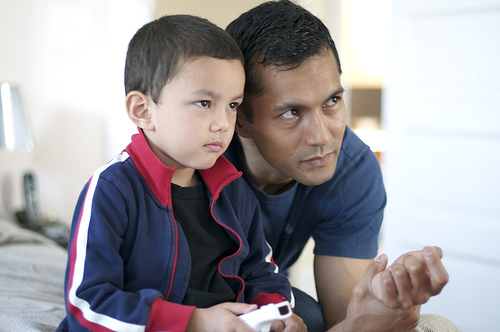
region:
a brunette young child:
[63, 14, 295, 325]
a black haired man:
[225, 6, 452, 325]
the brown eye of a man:
[279, 107, 294, 119]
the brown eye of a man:
[324, 93, 340, 106]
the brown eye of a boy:
[193, 97, 207, 109]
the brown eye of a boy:
[229, 100, 241, 110]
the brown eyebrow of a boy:
[194, 84, 217, 100]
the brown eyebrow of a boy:
[230, 93, 243, 103]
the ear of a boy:
[127, 90, 159, 127]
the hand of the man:
[347, 247, 420, 329]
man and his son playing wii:
[112, 7, 387, 252]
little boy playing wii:
[116, 7, 286, 329]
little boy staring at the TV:
[112, 12, 242, 182]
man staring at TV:
[235, 12, 454, 291]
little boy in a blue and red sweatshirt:
[83, 12, 248, 312]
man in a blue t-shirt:
[238, 4, 408, 285]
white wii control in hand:
[227, 295, 300, 327]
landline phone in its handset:
[16, 163, 55, 226]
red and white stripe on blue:
[66, 178, 102, 319]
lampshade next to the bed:
[5, 78, 38, 154]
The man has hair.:
[225, 0, 355, 197]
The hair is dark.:
[215, 2, 361, 194]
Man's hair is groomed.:
[217, 2, 347, 171]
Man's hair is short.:
[216, 0, 366, 190]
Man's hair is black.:
[221, 0, 356, 189]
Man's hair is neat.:
[215, 1, 354, 197]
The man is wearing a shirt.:
[213, 0, 393, 298]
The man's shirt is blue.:
[214, 0, 392, 300]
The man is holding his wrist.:
[223, 0, 459, 330]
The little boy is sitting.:
[27, 9, 313, 329]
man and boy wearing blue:
[89, 18, 442, 312]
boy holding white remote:
[105, 41, 331, 328]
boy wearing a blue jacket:
[96, 32, 318, 322]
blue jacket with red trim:
[65, 142, 325, 328]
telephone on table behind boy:
[19, 163, 81, 264]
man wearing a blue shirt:
[236, 114, 425, 288]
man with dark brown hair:
[218, 6, 385, 203]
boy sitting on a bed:
[11, 17, 263, 329]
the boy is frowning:
[108, 18, 260, 175]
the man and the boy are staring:
[78, 3, 406, 204]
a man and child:
[75, 0, 488, 330]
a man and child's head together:
[40, 10, 419, 330]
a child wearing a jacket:
[51, 18, 325, 328]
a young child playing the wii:
[75, 5, 290, 328]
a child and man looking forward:
[104, 13, 474, 330]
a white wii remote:
[211, 268, 304, 330]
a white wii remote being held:
[194, 275, 321, 331]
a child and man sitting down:
[30, 9, 495, 313]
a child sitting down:
[76, 6, 310, 323]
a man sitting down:
[216, 7, 440, 327]